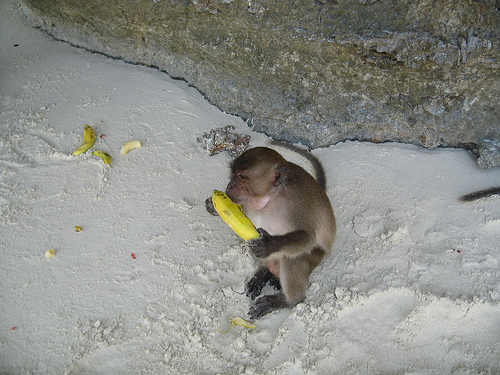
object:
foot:
[247, 291, 289, 319]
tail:
[267, 138, 326, 189]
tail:
[458, 187, 499, 203]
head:
[225, 146, 288, 206]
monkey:
[208, 145, 340, 310]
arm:
[246, 219, 341, 270]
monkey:
[236, 129, 396, 311]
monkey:
[205, 138, 341, 337]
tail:
[258, 127, 342, 195]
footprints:
[103, 256, 230, 336]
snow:
[16, 67, 493, 353]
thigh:
[271, 258, 319, 306]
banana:
[212, 188, 262, 245]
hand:
[200, 195, 220, 215]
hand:
[243, 227, 274, 259]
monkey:
[196, 137, 336, 319]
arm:
[245, 225, 315, 257]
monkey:
[205, 131, 340, 321]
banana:
[204, 180, 272, 245]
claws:
[244, 267, 279, 320]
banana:
[205, 191, 267, 258]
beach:
[377, 233, 467, 350]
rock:
[326, 18, 473, 135]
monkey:
[218, 123, 350, 326]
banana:
[202, 179, 274, 254]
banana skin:
[226, 315, 256, 332]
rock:
[359, 123, 374, 154]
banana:
[209, 183, 263, 242]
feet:
[245, 266, 280, 317]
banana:
[206, 182, 267, 249]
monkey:
[218, 148, 338, 311]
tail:
[267, 135, 334, 189]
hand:
[240, 225, 325, 259]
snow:
[8, 17, 496, 364]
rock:
[133, 0, 455, 155]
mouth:
[224, 190, 243, 205]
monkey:
[192, 133, 358, 323]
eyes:
[226, 165, 253, 181]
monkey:
[237, 160, 329, 304]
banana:
[207, 185, 257, 240]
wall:
[121, 19, 455, 194]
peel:
[72, 123, 112, 165]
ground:
[1, 0, 497, 373]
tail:
[276, 136, 330, 184]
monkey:
[227, 138, 327, 314]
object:
[193, 122, 250, 166]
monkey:
[213, 128, 344, 318]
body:
[238, 165, 338, 260]